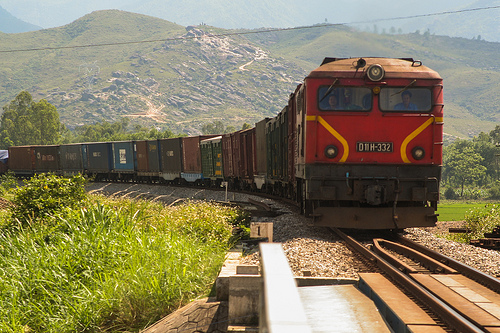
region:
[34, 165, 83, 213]
a tree in a distance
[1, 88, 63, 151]
a tree in a distance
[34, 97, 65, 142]
a tree in a distance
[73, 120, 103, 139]
a tree in a distance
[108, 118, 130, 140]
a tree in a distance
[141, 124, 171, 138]
a tree in a distance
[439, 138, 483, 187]
a tree in a distance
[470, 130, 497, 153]
a tree in a distance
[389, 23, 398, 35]
a tree in a distance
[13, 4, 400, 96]
The mountains are behind the train.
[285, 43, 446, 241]
The front of the train is red and yellow.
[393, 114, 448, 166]
The stripe on the train is yellow.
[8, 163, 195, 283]
The grass is green.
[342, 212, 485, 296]
The train tracks are brown.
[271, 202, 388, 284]
The gravel is under the train.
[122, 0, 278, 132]
The rocks are on the hill.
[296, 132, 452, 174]
The headlights are off.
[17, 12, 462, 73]
The wire above the train is black.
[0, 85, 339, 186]
The train is very long.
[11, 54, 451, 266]
a train is moving down the tracks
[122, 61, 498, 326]
the train is approaching a trestle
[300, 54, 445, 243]
the front of the train is red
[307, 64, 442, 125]
the engine's windows have windshield wipers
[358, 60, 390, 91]
the train's horn is above the engine's windows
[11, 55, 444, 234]
the train is pulling freight cars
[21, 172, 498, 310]
the tracks have a gravel bed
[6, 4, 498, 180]
hills and mountains are behind the train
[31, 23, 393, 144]
the ridge behind the train is rocky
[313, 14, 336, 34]
a tower is on top of the mountain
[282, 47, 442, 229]
A red engine pulling a train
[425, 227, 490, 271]
Gravel along a train track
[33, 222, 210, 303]
Grass growing tall along a train track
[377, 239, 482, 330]
The rails of a train track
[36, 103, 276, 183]
A line of cars pulled behind an engine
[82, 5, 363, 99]
A mountain in the background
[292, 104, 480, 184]
Yellow stripes on the front of a red engine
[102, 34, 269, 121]
A rocky hillside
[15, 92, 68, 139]
Trees behind a train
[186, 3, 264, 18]
A grey blue sky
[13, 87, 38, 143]
a tree in a distance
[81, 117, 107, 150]
a tree in a distance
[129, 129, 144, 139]
a tree in a distance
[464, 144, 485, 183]
a tree in a distance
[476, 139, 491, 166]
a tree in a distance